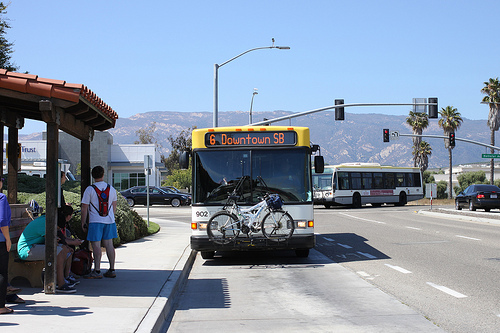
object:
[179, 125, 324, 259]
city bus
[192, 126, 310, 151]
yellow trim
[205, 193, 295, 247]
bike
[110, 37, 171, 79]
clouds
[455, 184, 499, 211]
car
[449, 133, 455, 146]
stoplight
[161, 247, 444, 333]
street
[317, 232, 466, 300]
stripes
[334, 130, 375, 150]
mountains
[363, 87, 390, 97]
background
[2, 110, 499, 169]
hills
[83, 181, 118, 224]
tshirt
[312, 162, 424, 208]
bus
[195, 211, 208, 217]
number 902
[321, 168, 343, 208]
turn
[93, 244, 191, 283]
sidewalk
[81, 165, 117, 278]
man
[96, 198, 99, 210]
back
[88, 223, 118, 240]
shorts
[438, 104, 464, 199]
palm tree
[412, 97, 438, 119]
sign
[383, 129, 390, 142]
traffic signal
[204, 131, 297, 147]
display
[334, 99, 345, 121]
streetlights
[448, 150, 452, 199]
pole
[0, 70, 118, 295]
bus stop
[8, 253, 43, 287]
bench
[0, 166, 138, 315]
people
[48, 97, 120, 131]
bus top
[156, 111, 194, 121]
mountain range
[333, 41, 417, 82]
sky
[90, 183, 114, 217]
backpack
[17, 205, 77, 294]
person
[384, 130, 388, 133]
light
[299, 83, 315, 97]
distance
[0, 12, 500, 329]
downtown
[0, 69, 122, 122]
roof